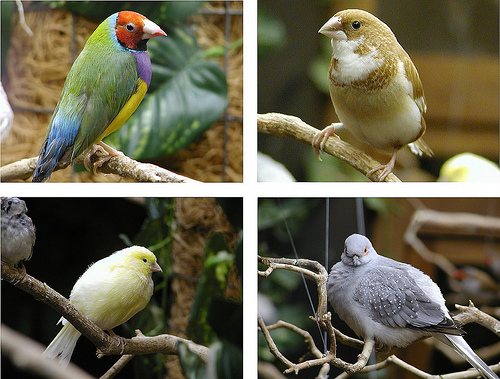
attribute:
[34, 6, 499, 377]
birds — perched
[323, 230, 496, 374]
feathers — grey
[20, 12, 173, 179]
bird — multicolored, tropical, colorful, perched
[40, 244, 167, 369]
bird — yellow, small, light yellow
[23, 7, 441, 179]
birds — perched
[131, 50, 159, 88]
feathers — purple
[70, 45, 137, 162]
wing — green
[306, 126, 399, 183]
tallons — sharp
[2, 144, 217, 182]
branch — brown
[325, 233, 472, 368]
bird — grey, lavender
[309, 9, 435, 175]
bird — white, brown, cream, light brown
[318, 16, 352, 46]
beak — white, tan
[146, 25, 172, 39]
beak — pink, red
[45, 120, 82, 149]
feathers — blue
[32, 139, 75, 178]
tail — multicolored, blue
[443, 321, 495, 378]
tail — grey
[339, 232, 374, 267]
head — gray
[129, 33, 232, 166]
leaf — green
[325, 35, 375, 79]
patch — white